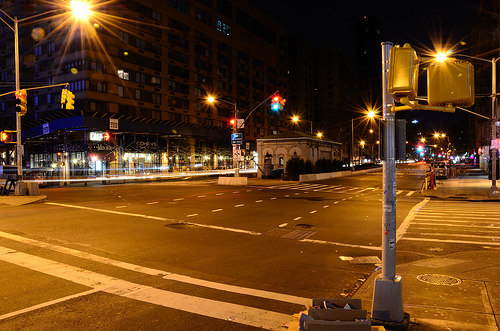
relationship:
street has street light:
[0, 156, 499, 327] [199, 84, 292, 181]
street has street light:
[0, 156, 499, 327] [3, 2, 112, 197]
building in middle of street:
[254, 127, 343, 180] [0, 156, 499, 327]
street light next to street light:
[3, 2, 112, 197] [199, 84, 292, 181]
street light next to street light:
[3, 0, 112, 197] [3, 0, 112, 197]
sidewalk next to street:
[427, 154, 500, 201] [0, 156, 499, 327]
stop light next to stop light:
[228, 116, 240, 136] [269, 92, 282, 112]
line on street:
[43, 196, 386, 267] [0, 156, 499, 327]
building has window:
[2, 2, 318, 173] [119, 67, 138, 82]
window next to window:
[119, 67, 138, 82] [119, 67, 138, 82]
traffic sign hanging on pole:
[232, 132, 245, 146] [232, 101, 243, 175]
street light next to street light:
[199, 84, 292, 181] [3, 0, 112, 197]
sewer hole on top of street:
[168, 220, 197, 231] [0, 156, 499, 327]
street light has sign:
[199, 84, 292, 181] [232, 132, 245, 146]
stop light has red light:
[269, 92, 282, 112] [273, 94, 278, 102]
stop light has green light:
[269, 92, 282, 112] [272, 104, 281, 113]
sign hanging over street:
[3, 132, 13, 142] [0, 156, 499, 327]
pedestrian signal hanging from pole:
[65, 89, 74, 108] [232, 101, 243, 178]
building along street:
[254, 127, 343, 180] [0, 156, 499, 327]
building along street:
[2, 2, 318, 173] [0, 156, 499, 327]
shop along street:
[28, 141, 257, 172] [0, 156, 499, 327]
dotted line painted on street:
[117, 181, 276, 210] [0, 156, 499, 327]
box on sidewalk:
[454, 167, 464, 175] [427, 154, 500, 201]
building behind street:
[2, 2, 318, 173] [0, 156, 499, 327]